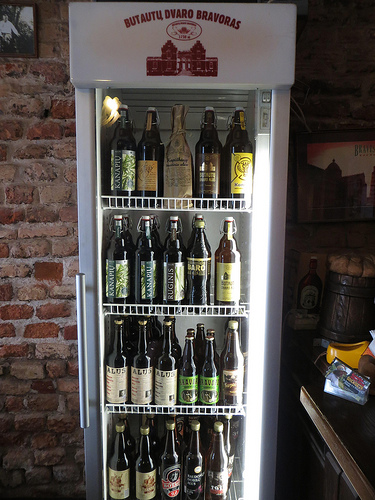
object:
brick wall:
[0, 55, 84, 500]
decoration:
[316, 251, 375, 344]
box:
[285, 245, 327, 330]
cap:
[185, 335, 195, 341]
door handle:
[75, 273, 90, 428]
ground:
[286, 84, 344, 137]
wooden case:
[278, 309, 374, 500]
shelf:
[103, 303, 248, 317]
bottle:
[132, 214, 161, 315]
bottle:
[161, 215, 188, 314]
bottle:
[185, 213, 212, 313]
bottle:
[105, 318, 130, 407]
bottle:
[177, 335, 200, 413]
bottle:
[198, 335, 220, 413]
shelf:
[106, 403, 247, 415]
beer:
[220, 105, 253, 210]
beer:
[195, 105, 224, 208]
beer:
[163, 103, 194, 209]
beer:
[136, 106, 165, 208]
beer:
[108, 99, 137, 207]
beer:
[213, 215, 241, 314]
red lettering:
[123, 8, 242, 41]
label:
[199, 375, 221, 405]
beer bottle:
[130, 319, 155, 413]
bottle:
[154, 319, 179, 412]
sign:
[303, 140, 374, 220]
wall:
[289, 0, 373, 248]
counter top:
[280, 345, 375, 491]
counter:
[281, 325, 374, 500]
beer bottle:
[107, 104, 138, 208]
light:
[102, 94, 122, 128]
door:
[80, 82, 271, 500]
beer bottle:
[102, 207, 134, 313]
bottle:
[194, 101, 222, 200]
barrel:
[316, 262, 374, 342]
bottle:
[136, 106, 165, 207]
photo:
[0, 1, 38, 58]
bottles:
[204, 415, 237, 500]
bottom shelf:
[106, 411, 245, 500]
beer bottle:
[214, 216, 242, 315]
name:
[123, 8, 241, 78]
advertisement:
[123, 8, 242, 78]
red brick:
[34, 261, 63, 281]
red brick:
[23, 321, 60, 339]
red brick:
[26, 118, 64, 140]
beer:
[107, 422, 130, 500]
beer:
[134, 424, 156, 500]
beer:
[156, 420, 182, 500]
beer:
[182, 419, 206, 500]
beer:
[204, 421, 229, 500]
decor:
[312, 340, 369, 373]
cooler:
[68, 1, 297, 498]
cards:
[325, 356, 372, 402]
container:
[324, 378, 369, 406]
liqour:
[293, 322, 331, 391]